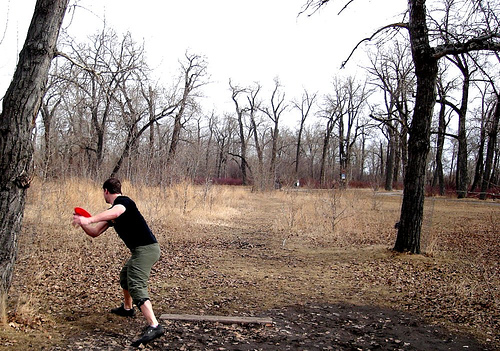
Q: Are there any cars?
A: No, there are no cars.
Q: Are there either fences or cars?
A: No, there are no cars or fences.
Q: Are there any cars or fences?
A: No, there are no cars or fences.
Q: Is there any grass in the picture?
A: Yes, there is grass.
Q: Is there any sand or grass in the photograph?
A: Yes, there is grass.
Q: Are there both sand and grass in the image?
A: No, there is grass but no sand.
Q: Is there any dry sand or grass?
A: Yes, there is dry grass.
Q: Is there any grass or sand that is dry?
A: Yes, the grass is dry.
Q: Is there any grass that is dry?
A: Yes, there is dry grass.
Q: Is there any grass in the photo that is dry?
A: Yes, there is grass that is dry.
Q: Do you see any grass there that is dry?
A: Yes, there is grass that is dry.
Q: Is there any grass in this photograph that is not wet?
A: Yes, there is dry grass.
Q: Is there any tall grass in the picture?
A: Yes, there is tall grass.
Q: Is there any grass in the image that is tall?
A: Yes, there is grass that is tall.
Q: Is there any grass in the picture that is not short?
A: Yes, there is tall grass.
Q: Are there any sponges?
A: No, there are no sponges.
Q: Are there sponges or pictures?
A: No, there are no sponges or pictures.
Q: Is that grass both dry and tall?
A: Yes, the grass is dry and tall.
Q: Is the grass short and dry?
A: No, the grass is dry but tall.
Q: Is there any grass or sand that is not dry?
A: No, there is grass but it is dry.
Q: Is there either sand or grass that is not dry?
A: No, there is grass but it is dry.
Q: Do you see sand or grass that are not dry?
A: No, there is grass but it is dry.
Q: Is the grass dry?
A: Yes, the grass is dry.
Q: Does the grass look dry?
A: Yes, the grass is dry.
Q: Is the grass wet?
A: No, the grass is dry.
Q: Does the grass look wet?
A: No, the grass is dry.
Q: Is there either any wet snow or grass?
A: No, there is grass but it is dry.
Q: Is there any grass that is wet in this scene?
A: No, there is grass but it is dry.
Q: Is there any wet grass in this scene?
A: No, there is grass but it is dry.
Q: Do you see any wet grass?
A: No, there is grass but it is dry.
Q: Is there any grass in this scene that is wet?
A: No, there is grass but it is dry.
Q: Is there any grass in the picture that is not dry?
A: No, there is grass but it is dry.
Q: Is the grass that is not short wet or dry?
A: The grass is dry.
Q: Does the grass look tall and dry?
A: Yes, the grass is tall and dry.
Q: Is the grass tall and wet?
A: No, the grass is tall but dry.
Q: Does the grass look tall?
A: Yes, the grass is tall.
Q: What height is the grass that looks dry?
A: The grass is tall.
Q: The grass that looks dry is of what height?
A: The grass is tall.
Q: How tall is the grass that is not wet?
A: The grass is tall.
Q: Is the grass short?
A: No, the grass is tall.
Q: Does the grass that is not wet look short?
A: No, the grass is tall.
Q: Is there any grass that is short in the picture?
A: No, there is grass but it is tall.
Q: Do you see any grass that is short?
A: No, there is grass but it is tall.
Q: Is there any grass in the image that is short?
A: No, there is grass but it is tall.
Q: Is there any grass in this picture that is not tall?
A: No, there is grass but it is tall.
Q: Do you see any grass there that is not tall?
A: No, there is grass but it is tall.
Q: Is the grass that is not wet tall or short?
A: The grass is tall.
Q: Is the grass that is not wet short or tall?
A: The grass is tall.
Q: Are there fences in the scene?
A: No, there are no fences.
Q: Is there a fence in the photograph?
A: No, there are no fences.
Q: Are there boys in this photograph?
A: No, there are no boys.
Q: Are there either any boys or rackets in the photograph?
A: No, there are no boys or rackets.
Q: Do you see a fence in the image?
A: No, there are no fences.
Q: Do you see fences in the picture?
A: No, there are no fences.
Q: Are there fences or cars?
A: No, there are no fences or cars.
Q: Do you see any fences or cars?
A: No, there are no fences or cars.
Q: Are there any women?
A: No, there are no women.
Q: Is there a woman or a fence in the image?
A: No, there are no women or fences.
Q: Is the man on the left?
A: Yes, the man is on the left of the image.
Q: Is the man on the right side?
A: No, the man is on the left of the image.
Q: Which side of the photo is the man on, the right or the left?
A: The man is on the left of the image.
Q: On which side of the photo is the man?
A: The man is on the left of the image.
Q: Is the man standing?
A: Yes, the man is standing.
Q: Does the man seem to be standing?
A: Yes, the man is standing.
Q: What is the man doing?
A: The man is standing.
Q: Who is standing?
A: The man is standing.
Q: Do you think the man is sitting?
A: No, the man is standing.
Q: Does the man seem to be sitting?
A: No, the man is standing.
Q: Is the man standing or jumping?
A: The man is standing.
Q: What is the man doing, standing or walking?
A: The man is standing.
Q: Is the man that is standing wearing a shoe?
A: Yes, the man is wearing a shoe.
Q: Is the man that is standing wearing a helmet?
A: No, the man is wearing a shoe.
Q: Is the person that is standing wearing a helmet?
A: No, the man is wearing a shoe.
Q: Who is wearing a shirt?
A: The man is wearing a shirt.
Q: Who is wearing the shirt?
A: The man is wearing a shirt.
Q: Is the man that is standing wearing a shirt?
A: Yes, the man is wearing a shirt.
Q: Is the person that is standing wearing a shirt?
A: Yes, the man is wearing a shirt.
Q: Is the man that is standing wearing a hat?
A: No, the man is wearing a shirt.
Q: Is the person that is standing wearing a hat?
A: No, the man is wearing a shirt.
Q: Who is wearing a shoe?
A: The man is wearing a shoe.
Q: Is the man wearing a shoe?
A: Yes, the man is wearing a shoe.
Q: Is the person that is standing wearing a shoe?
A: Yes, the man is wearing a shoe.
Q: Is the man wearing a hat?
A: No, the man is wearing a shoe.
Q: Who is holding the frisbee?
A: The man is holding the frisbee.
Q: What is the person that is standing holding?
A: The man is holding the frisbee.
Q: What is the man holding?
A: The man is holding the frisbee.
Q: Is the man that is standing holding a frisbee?
A: Yes, the man is holding a frisbee.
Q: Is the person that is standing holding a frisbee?
A: Yes, the man is holding a frisbee.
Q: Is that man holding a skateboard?
A: No, the man is holding a frisbee.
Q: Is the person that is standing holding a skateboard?
A: No, the man is holding a frisbee.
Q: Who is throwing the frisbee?
A: The man is throwing the frisbee.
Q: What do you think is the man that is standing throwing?
A: The man is throwing the frisbee.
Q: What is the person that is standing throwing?
A: The man is throwing the frisbee.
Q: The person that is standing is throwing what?
A: The man is throwing the frisbee.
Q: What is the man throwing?
A: The man is throwing the frisbee.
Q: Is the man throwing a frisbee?
A: Yes, the man is throwing a frisbee.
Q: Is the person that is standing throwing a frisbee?
A: Yes, the man is throwing a frisbee.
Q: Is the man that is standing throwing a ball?
A: No, the man is throwing a frisbee.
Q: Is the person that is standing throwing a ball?
A: No, the man is throwing a frisbee.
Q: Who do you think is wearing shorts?
A: The man is wearing shorts.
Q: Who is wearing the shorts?
A: The man is wearing shorts.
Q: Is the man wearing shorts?
A: Yes, the man is wearing shorts.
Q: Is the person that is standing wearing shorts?
A: Yes, the man is wearing shorts.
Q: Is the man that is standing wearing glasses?
A: No, the man is wearing shorts.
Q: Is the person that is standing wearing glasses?
A: No, the man is wearing shorts.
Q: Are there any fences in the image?
A: No, there are no fences.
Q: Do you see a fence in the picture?
A: No, there are no fences.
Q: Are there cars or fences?
A: No, there are no fences or cars.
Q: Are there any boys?
A: No, there are no boys.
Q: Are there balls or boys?
A: No, there are no boys or balls.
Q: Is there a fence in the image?
A: No, there are no fences.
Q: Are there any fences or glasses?
A: No, there are no fences or glasses.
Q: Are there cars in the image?
A: No, there are no cars.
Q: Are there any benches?
A: No, there are no benches.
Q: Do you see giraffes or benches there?
A: No, there are no benches or giraffes.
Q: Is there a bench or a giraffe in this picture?
A: No, there are no benches or giraffes.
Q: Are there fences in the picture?
A: No, there are no fences.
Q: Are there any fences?
A: No, there are no fences.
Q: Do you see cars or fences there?
A: No, there are no fences or cars.